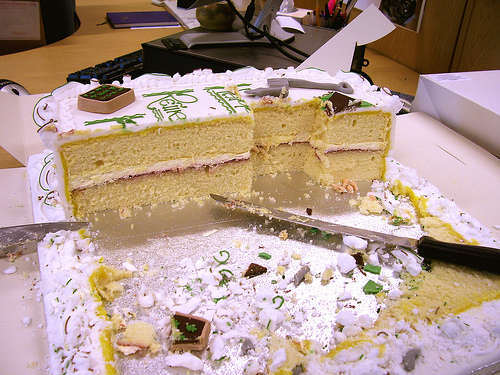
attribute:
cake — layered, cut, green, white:
[26, 102, 399, 226]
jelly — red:
[98, 167, 187, 183]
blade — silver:
[224, 197, 382, 251]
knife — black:
[257, 199, 499, 278]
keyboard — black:
[89, 52, 149, 77]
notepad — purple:
[101, 4, 179, 32]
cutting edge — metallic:
[235, 209, 289, 228]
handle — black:
[427, 230, 493, 261]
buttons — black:
[100, 63, 133, 70]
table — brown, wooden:
[17, 27, 175, 52]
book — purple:
[129, 2, 164, 28]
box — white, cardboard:
[415, 85, 495, 171]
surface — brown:
[14, 16, 126, 69]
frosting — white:
[146, 80, 246, 117]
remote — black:
[79, 56, 148, 94]